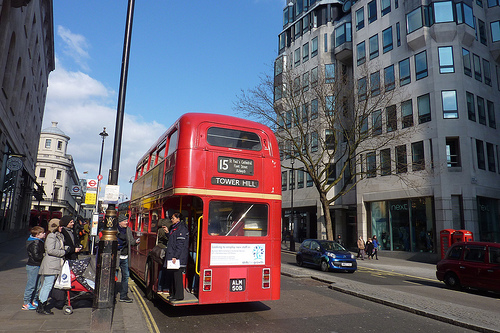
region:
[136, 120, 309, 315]
red large double decker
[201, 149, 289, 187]
number 15 on display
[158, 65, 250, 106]
blue sky with no clouds visible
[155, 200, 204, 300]
bus operator at stairs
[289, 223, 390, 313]
blue small sports car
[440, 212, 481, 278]
red call boxes on sidewalk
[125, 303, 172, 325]
two yellow double lines on ground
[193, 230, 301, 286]
white sign in front of bus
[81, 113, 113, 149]
metal pointy shaped street light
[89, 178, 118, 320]
black and gold designed street lamp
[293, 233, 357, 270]
blue car driving down street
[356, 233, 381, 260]
group of people on sidewalk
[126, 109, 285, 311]
red double decker bus on street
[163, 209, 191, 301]
man in jacket standing on bus platform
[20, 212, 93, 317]
group of people waiting for bus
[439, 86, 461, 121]
window in building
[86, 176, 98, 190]
sign on pole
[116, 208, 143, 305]
man standing next to bus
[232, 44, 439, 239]
tree without leaves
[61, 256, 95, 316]
stroller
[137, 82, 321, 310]
red bus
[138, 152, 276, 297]
red bus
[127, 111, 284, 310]
Double decker red bus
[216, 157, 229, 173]
Number 15 on red bus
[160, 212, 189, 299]
Woman standing on bus platform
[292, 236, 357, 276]
Small blue car passing red bus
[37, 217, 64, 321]
Woman pushing stroller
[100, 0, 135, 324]
Black metal post by red bus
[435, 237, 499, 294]
Red car in front of blue car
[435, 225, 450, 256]
Red telephone booth by building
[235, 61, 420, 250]
Big bare tree by building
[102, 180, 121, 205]
Sign on black metal post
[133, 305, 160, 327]
the line is yellow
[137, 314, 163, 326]
the line is yellow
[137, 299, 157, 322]
the line is yellow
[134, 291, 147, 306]
the line is yellow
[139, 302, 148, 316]
the line is yellow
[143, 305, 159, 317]
the line is yellow